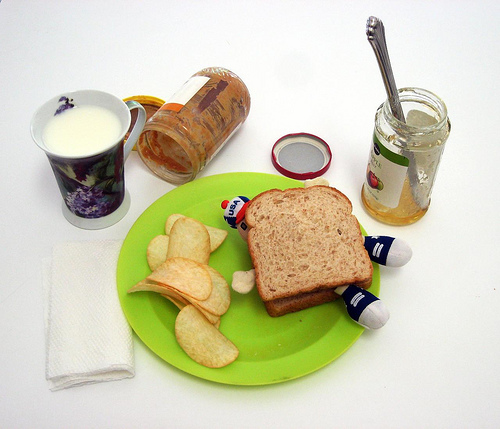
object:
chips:
[126, 213, 257, 368]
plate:
[117, 171, 380, 386]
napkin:
[46, 239, 136, 392]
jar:
[136, 66, 251, 186]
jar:
[359, 86, 451, 226]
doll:
[221, 176, 413, 329]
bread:
[245, 185, 374, 317]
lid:
[271, 132, 332, 180]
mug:
[30, 88, 147, 230]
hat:
[221, 196, 254, 229]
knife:
[365, 15, 429, 209]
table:
[0, 0, 500, 429]